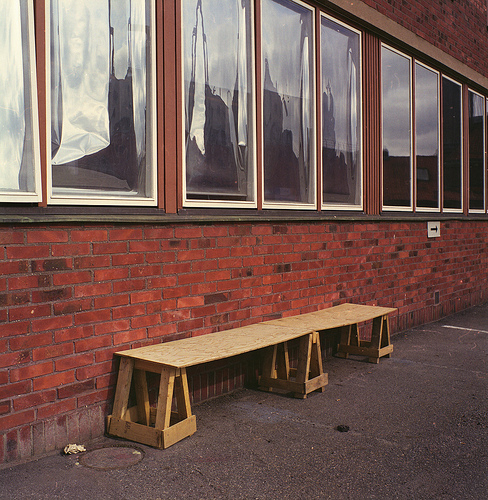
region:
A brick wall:
[1, 233, 487, 303]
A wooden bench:
[102, 286, 415, 459]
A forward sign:
[424, 218, 459, 258]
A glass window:
[380, 41, 451, 227]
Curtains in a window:
[40, 6, 154, 162]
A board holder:
[97, 352, 236, 453]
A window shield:
[5, 176, 456, 226]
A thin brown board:
[113, 294, 403, 343]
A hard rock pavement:
[238, 391, 467, 497]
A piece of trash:
[61, 432, 90, 461]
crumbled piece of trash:
[44, 431, 106, 493]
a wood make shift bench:
[119, 334, 483, 360]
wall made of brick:
[14, 374, 78, 471]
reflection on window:
[182, 9, 260, 232]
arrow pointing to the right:
[418, 220, 470, 262]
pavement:
[183, 468, 323, 499]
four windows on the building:
[377, 23, 486, 250]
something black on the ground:
[318, 408, 396, 478]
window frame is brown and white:
[309, 5, 391, 168]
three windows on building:
[189, 140, 361, 239]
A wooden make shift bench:
[89, 295, 445, 460]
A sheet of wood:
[107, 270, 409, 400]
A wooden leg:
[93, 337, 230, 469]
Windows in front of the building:
[1, 8, 487, 235]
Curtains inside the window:
[175, 3, 254, 164]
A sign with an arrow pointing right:
[418, 213, 458, 241]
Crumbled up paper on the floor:
[47, 443, 95, 458]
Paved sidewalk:
[1, 307, 484, 498]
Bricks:
[85, 270, 134, 286]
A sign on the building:
[385, 185, 467, 271]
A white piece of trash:
[52, 437, 95, 460]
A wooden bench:
[94, 294, 416, 446]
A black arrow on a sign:
[429, 225, 438, 231]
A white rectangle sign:
[424, 215, 447, 240]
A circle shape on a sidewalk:
[76, 439, 150, 471]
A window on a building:
[372, 37, 418, 218]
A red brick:
[49, 269, 97, 284]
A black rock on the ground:
[333, 420, 351, 438]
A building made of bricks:
[28, 2, 484, 437]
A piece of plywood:
[112, 313, 313, 364]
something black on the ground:
[327, 411, 386, 456]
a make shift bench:
[116, 351, 448, 427]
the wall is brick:
[35, 272, 100, 352]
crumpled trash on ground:
[64, 441, 116, 485]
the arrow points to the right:
[421, 215, 464, 258]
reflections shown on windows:
[392, 117, 459, 213]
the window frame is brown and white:
[399, 28, 436, 135]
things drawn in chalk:
[408, 334, 477, 398]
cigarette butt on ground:
[326, 383, 380, 439]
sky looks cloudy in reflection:
[365, 87, 483, 203]